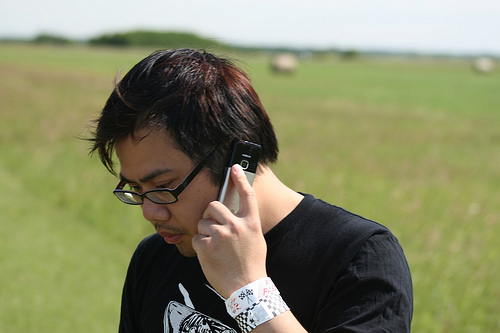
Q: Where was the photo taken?
A: It was taken at the field.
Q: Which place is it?
A: It is a field.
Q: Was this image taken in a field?
A: Yes, it was taken in a field.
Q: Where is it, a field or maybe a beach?
A: It is a field.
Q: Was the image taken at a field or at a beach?
A: It was taken at a field.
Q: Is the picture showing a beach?
A: No, the picture is showing a field.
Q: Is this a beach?
A: No, it is a field.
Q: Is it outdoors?
A: Yes, it is outdoors.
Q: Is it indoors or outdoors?
A: It is outdoors.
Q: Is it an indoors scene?
A: No, it is outdoors.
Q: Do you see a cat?
A: No, there are no cats.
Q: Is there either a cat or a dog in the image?
A: No, there are no cats or dogs.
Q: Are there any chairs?
A: No, there are no chairs.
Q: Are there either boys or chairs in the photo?
A: No, there are no chairs or boys.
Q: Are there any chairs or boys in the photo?
A: No, there are no chairs or boys.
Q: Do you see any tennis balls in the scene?
A: No, there are no tennis balls.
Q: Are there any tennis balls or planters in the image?
A: No, there are no tennis balls or planters.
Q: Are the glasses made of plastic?
A: Yes, the glasses are made of plastic.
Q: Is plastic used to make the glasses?
A: Yes, the glasses are made of plastic.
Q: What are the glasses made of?
A: The glasses are made of plastic.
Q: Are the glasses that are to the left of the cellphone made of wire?
A: No, the glasses are made of plastic.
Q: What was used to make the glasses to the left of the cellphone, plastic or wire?
A: The glasses are made of plastic.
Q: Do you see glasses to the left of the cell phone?
A: Yes, there are glasses to the left of the cell phone.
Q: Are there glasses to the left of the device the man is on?
A: Yes, there are glasses to the left of the cell phone.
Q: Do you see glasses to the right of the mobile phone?
A: No, the glasses are to the left of the mobile phone.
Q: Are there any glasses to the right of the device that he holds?
A: No, the glasses are to the left of the mobile phone.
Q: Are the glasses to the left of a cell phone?
A: Yes, the glasses are to the left of a cell phone.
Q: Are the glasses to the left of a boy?
A: No, the glasses are to the left of a cell phone.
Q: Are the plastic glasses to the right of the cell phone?
A: No, the glasses are to the left of the cell phone.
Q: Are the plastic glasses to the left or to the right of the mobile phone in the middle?
A: The glasses are to the left of the cell phone.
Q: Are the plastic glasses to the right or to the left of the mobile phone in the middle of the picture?
A: The glasses are to the left of the cell phone.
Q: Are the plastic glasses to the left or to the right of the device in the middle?
A: The glasses are to the left of the cell phone.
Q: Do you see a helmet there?
A: No, there are no helmets.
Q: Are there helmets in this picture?
A: No, there are no helmets.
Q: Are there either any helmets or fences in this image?
A: No, there are no helmets or fences.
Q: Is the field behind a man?
A: Yes, the field is behind a man.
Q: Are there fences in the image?
A: No, there are no fences.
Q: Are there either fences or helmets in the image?
A: No, there are no fences or helmets.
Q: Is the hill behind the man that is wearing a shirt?
A: Yes, the hill is behind the man.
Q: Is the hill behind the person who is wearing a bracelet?
A: Yes, the hill is behind the man.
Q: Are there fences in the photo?
A: No, there are no fences.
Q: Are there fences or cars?
A: No, there are no fences or cars.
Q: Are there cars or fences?
A: No, there are no fences or cars.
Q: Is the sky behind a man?
A: Yes, the sky is behind a man.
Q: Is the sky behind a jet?
A: No, the sky is behind a man.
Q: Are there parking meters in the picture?
A: No, there are no parking meters.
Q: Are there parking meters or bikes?
A: No, there are no parking meters or bikes.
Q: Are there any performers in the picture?
A: No, there are no performers.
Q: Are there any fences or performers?
A: No, there are no performers or fences.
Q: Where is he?
A: The man is in the field.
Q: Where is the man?
A: The man is in the field.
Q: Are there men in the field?
A: Yes, there is a man in the field.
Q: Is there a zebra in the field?
A: No, there is a man in the field.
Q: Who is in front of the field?
A: The man is in front of the field.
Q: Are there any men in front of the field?
A: Yes, there is a man in front of the field.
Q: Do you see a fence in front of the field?
A: No, there is a man in front of the field.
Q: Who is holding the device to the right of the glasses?
A: The man is holding the cell phone.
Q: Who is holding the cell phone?
A: The man is holding the cell phone.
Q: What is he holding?
A: The man is holding the cellphone.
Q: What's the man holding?
A: The man is holding the cellphone.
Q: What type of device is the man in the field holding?
A: The man is holding the mobile phone.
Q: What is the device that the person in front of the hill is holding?
A: The device is a cell phone.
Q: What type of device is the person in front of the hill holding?
A: The man is holding the mobile phone.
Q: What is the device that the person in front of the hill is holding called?
A: The device is a cell phone.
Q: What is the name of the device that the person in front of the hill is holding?
A: The device is a cell phone.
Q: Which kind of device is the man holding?
A: The man is holding the mobile phone.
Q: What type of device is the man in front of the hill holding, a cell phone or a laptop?
A: The man is holding a cell phone.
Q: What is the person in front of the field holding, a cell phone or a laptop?
A: The man is holding a cell phone.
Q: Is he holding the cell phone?
A: Yes, the man is holding the cell phone.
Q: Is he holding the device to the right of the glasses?
A: Yes, the man is holding the cell phone.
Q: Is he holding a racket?
A: No, the man is holding the cell phone.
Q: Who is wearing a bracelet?
A: The man is wearing a bracelet.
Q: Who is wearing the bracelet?
A: The man is wearing a bracelet.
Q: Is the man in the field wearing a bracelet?
A: Yes, the man is wearing a bracelet.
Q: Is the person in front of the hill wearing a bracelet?
A: Yes, the man is wearing a bracelet.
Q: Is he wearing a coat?
A: No, the man is wearing a bracelet.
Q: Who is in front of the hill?
A: The man is in front of the hill.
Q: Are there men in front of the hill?
A: Yes, there is a man in front of the hill.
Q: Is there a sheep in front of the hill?
A: No, there is a man in front of the hill.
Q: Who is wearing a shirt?
A: The man is wearing a shirt.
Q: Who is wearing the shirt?
A: The man is wearing a shirt.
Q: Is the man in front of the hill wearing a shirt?
A: Yes, the man is wearing a shirt.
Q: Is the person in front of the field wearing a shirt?
A: Yes, the man is wearing a shirt.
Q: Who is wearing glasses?
A: The man is wearing glasses.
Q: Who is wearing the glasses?
A: The man is wearing glasses.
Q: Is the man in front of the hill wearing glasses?
A: Yes, the man is wearing glasses.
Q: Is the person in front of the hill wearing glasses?
A: Yes, the man is wearing glasses.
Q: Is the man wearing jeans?
A: No, the man is wearing glasses.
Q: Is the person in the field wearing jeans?
A: No, the man is wearing glasses.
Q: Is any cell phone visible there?
A: Yes, there is a cell phone.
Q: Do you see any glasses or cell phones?
A: Yes, there is a cell phone.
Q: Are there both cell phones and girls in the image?
A: No, there is a cell phone but no girls.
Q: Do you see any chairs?
A: No, there are no chairs.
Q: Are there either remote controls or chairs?
A: No, there are no chairs or remote controls.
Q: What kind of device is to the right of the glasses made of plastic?
A: The device is a cell phone.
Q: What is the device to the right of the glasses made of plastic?
A: The device is a cell phone.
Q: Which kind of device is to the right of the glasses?
A: The device is a cell phone.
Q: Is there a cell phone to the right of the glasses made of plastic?
A: Yes, there is a cell phone to the right of the glasses.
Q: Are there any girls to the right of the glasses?
A: No, there is a cell phone to the right of the glasses.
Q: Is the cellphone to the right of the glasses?
A: Yes, the cellphone is to the right of the glasses.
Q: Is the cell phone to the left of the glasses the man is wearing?
A: No, the cell phone is to the right of the glasses.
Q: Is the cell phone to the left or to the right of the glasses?
A: The cell phone is to the right of the glasses.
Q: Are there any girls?
A: No, there are no girls.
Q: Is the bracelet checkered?
A: Yes, the bracelet is checkered.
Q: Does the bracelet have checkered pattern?
A: Yes, the bracelet is checkered.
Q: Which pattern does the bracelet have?
A: The bracelet has checkered pattern.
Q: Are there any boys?
A: No, there are no boys.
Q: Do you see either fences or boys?
A: No, there are no boys or fences.